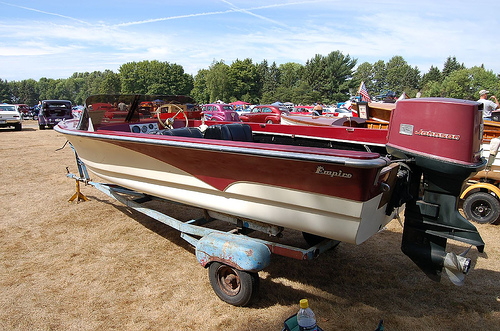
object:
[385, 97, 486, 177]
engine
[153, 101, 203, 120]
car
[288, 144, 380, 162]
floor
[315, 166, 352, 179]
brand name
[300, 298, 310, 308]
top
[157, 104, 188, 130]
steering wheel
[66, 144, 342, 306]
boat trailer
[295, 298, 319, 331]
bottle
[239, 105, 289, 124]
car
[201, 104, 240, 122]
car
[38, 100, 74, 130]
car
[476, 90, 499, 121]
man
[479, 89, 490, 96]
cap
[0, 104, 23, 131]
car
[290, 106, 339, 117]
cars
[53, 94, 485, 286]
boat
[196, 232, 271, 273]
mudgear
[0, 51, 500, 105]
trees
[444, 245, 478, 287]
propeller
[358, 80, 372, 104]
flag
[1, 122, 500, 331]
grass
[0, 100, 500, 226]
cars